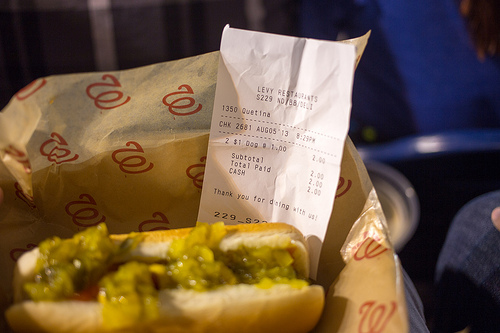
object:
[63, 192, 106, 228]
logo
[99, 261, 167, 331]
hot dog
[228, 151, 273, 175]
order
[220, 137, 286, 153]
words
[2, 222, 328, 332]
bun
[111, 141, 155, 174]
letter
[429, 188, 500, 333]
blue jeans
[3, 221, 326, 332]
food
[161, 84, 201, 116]
w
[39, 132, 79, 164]
w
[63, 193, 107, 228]
w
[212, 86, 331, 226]
paper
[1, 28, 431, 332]
brown paper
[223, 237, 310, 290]
hot dog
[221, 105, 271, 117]
writing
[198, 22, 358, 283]
purchase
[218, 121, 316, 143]
writing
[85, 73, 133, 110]
w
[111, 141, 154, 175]
w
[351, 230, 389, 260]
w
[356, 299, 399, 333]
w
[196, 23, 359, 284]
receipt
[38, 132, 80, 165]
liner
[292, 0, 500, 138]
shirt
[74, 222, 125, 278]
hot dog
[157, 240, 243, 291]
hotdog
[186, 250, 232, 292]
mustard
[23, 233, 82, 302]
hot dog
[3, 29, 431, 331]
package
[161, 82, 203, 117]
letter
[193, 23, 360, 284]
receip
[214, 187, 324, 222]
english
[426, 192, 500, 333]
man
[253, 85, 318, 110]
name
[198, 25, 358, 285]
recipe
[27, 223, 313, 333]
relish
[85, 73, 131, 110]
logo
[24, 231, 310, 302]
inside